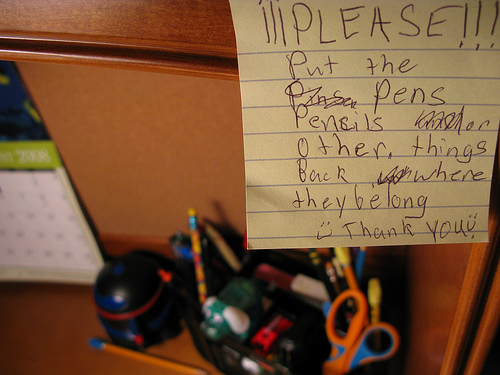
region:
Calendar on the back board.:
[5, 87, 87, 282]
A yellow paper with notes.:
[226, 10, 451, 251]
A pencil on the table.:
[89, 331, 186, 373]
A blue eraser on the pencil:
[74, 333, 108, 351]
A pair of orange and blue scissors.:
[323, 299, 383, 371]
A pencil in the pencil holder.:
[176, 206, 217, 314]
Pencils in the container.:
[313, 244, 399, 323]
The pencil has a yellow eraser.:
[371, 278, 383, 303]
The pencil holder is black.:
[184, 319, 285, 371]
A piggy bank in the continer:
[196, 285, 261, 338]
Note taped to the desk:
[221, 5, 491, 245]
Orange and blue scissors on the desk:
[325, 294, 399, 370]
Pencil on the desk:
[187, 211, 208, 297]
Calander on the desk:
[2, 141, 102, 286]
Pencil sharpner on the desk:
[255, 326, 275, 348]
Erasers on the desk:
[253, 264, 327, 297]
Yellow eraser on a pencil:
[367, 274, 382, 307]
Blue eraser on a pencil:
[83, 334, 107, 352]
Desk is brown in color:
[7, 293, 351, 374]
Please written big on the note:
[246, 3, 497, 49]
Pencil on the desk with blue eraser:
[83, 336, 208, 371]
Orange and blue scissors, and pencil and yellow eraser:
[320, 280, 395, 370]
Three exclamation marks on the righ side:
[452, 0, 497, 51]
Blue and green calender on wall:
[0, 56, 100, 281]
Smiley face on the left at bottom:
[312, 217, 334, 242]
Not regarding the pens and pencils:
[240, 0, 495, 246]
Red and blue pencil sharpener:
[92, 250, 166, 346]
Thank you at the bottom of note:
[342, 217, 465, 241]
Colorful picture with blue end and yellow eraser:
[190, 206, 207, 308]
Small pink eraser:
[252, 256, 297, 286]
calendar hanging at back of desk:
[1, 51, 491, 373]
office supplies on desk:
[90, 207, 403, 372]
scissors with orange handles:
[320, 288, 399, 374]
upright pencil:
[185, 204, 208, 304]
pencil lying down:
[87, 334, 211, 374]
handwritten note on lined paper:
[227, 1, 492, 250]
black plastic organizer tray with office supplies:
[182, 204, 400, 374]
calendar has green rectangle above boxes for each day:
[0, 60, 104, 285]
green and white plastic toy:
[197, 295, 249, 340]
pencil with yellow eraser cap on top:
[366, 277, 381, 324]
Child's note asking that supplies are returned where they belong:
[227, 0, 498, 252]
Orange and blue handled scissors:
[319, 284, 401, 372]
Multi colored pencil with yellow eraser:
[185, 207, 207, 307]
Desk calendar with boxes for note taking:
[1, 138, 107, 288]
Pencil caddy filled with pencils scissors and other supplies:
[180, 206, 408, 369]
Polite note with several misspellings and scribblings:
[230, 0, 498, 255]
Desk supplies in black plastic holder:
[180, 206, 410, 373]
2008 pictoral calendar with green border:
[0, 56, 115, 291]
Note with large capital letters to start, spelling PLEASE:
[225, 0, 498, 252]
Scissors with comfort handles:
[318, 288, 402, 374]